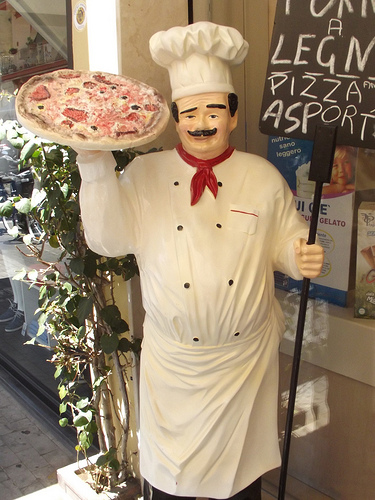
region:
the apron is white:
[141, 190, 288, 473]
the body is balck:
[274, 10, 374, 161]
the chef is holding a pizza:
[83, 28, 293, 491]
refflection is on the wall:
[295, 334, 351, 449]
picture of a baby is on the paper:
[332, 154, 354, 203]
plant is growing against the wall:
[43, 293, 141, 497]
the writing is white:
[285, 50, 370, 117]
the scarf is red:
[179, 160, 244, 189]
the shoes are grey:
[7, 304, 23, 329]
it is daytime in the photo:
[1, 80, 366, 492]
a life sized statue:
[2, 21, 312, 486]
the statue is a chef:
[53, 2, 306, 473]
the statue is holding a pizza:
[16, 1, 324, 496]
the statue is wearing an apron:
[89, 290, 307, 471]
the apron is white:
[93, 325, 290, 473]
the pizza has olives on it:
[11, 41, 164, 144]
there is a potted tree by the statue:
[0, 131, 140, 496]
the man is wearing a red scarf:
[146, 135, 243, 194]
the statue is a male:
[56, 19, 269, 196]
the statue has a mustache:
[174, 120, 234, 158]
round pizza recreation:
[14, 65, 174, 153]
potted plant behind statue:
[4, 128, 139, 498]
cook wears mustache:
[144, 16, 252, 217]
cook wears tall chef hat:
[138, 18, 261, 205]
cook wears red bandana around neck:
[131, 11, 259, 213]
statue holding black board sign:
[245, 2, 360, 486]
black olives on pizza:
[11, 64, 178, 154]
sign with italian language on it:
[261, 1, 369, 159]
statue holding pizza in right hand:
[13, 11, 341, 432]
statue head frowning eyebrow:
[133, 21, 258, 172]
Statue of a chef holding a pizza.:
[14, 10, 355, 475]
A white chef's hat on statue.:
[136, 15, 248, 150]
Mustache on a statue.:
[160, 50, 237, 160]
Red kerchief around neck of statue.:
[164, 96, 254, 203]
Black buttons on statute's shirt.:
[155, 170, 254, 348]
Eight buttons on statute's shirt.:
[157, 168, 250, 348]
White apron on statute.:
[121, 317, 294, 499]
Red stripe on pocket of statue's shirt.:
[223, 198, 266, 234]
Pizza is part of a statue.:
[15, 50, 167, 157]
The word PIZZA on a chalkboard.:
[261, 62, 361, 103]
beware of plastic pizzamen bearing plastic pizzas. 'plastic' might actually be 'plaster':
[7, 0, 335, 499]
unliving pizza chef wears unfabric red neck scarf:
[169, 138, 241, 211]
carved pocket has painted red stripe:
[224, 201, 261, 238]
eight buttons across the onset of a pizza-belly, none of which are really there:
[166, 172, 246, 349]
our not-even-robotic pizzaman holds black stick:
[268, 120, 343, 498]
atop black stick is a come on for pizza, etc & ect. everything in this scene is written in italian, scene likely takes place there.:
[252, 0, 373, 316]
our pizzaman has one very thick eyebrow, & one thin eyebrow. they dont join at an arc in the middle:
[168, 96, 229, 120]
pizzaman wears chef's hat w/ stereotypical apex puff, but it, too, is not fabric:
[139, 9, 251, 99]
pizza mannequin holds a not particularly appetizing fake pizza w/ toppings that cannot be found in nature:
[10, 59, 177, 162]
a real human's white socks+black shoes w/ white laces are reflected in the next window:
[0, 252, 34, 346]